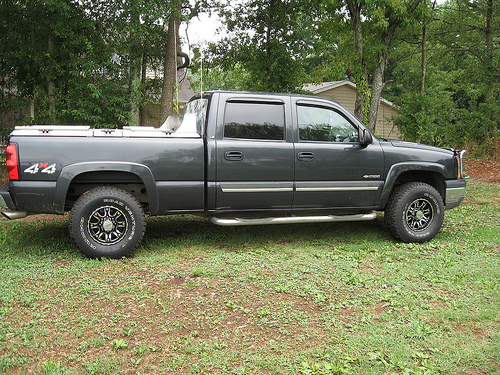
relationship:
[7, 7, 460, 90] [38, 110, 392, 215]
trees behind truck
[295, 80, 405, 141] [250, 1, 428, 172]
house behind tree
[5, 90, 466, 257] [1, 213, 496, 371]
pickup on grass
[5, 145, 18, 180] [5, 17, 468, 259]
light on pickup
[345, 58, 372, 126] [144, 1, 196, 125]
vine on tree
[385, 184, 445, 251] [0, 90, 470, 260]
tire on pickup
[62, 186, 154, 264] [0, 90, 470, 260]
tire on pickup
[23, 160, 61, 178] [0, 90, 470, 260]
4x4 on pickup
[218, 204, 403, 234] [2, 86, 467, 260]
board on chevy truck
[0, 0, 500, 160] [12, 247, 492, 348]
trees in yard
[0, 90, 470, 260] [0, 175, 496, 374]
pickup parked on grass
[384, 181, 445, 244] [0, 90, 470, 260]
tire on pickup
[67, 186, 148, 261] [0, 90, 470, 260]
tire on pickup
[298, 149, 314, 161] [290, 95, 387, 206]
handle on door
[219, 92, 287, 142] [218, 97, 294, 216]
window on door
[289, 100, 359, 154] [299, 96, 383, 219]
window on door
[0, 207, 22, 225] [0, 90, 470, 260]
muffler under pickup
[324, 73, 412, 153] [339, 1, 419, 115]
house behind tree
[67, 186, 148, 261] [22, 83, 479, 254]
tire on pickup